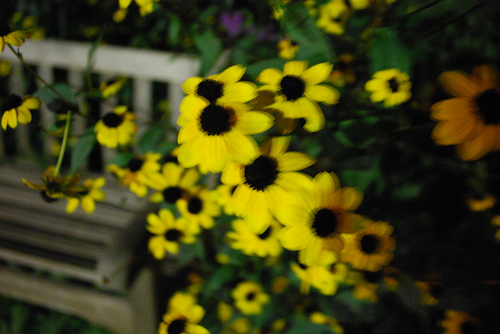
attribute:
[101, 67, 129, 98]
flower — Yellow , Black 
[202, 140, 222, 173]
petal — Yellow 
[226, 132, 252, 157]
petal — Yellow 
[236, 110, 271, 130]
petal — Yellow 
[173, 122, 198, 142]
petal — Yellow 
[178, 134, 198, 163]
petal — Yellow 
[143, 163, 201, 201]
flower — Yellow 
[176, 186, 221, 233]
yellow flower — Yellow 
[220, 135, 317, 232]
yellow flower — Yellow 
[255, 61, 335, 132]
yellow flower — Yellow 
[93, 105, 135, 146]
yellow flower — Yellow 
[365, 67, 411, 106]
yellow flower — Yellow 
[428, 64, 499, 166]
flower — Yellow 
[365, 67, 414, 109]
flower — Yellow 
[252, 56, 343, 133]
flower — Yellow 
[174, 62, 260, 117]
flower — Yellow 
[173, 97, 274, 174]
flower — Yellow 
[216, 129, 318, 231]
flower — Yellow 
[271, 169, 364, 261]
flower — Yellow 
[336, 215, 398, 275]
flower — Yellow 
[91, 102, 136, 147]
flower — Yellow 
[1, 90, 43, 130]
flower — Yellow 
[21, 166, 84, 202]
flower — Yellow 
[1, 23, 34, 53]
flower — Yellow 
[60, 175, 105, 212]
flower — Yellow 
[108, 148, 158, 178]
flower — Yellow 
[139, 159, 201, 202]
flower — Yellow 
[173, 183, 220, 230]
flower — Yellow 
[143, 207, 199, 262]
flower — Yellow 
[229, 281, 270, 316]
flower — Yellow 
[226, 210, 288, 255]
flower — Yellow 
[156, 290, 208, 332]
flower — Yellow 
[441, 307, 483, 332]
flower — Yellow 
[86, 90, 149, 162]
flower — Yellow 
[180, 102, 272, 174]
flower — Yellow 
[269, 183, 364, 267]
flower — Yellow 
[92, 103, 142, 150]
flower — Yellow 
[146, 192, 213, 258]
flower — Yellow , Black 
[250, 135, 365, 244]
flower — Yellow , Black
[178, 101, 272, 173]
flowers — Yellow 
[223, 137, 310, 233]
flowers — Yellow 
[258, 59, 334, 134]
flowers — Yellow 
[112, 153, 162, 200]
flowers — Yellow 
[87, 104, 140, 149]
flowers — Yellow 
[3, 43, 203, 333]
seating — Yellow 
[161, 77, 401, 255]
flower — Yellow 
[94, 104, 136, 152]
flower — Yellow 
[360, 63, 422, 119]
flower — yellow, black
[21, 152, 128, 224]
flower — Black , Yellow 